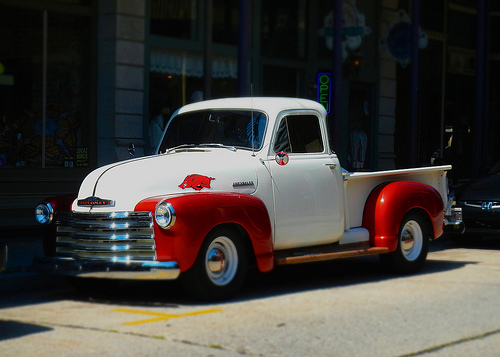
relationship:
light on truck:
[155, 200, 176, 229] [34, 95, 453, 295]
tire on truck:
[192, 216, 257, 296] [34, 95, 453, 295]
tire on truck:
[392, 206, 432, 267] [34, 95, 453, 295]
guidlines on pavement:
[97, 290, 227, 338] [0, 233, 500, 357]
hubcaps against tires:
[211, 240, 233, 281] [187, 271, 216, 294]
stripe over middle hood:
[88, 154, 111, 203] [71, 145, 171, 205]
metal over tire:
[361, 186, 444, 237] [377, 207, 434, 275]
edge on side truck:
[337, 156, 457, 177] [283, 128, 460, 247]